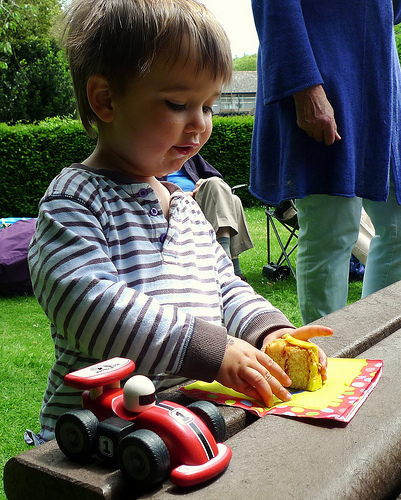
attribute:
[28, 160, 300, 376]
shirt — long sleeve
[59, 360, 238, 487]
car — toy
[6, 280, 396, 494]
table — brown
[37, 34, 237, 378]
boy — little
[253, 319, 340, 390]
cake — yellow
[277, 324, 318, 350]
frosting — yellow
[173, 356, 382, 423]
napkin — yellow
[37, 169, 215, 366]
stripes — shirt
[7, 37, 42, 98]
tree — large, green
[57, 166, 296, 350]
shirt — long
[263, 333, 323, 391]
cake — white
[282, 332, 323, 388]
frosting — yellow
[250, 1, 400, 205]
shirt — long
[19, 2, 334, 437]
boy — little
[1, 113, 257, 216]
bush — green, trimmed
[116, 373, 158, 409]
helmet — white, black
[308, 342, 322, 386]
frosting — yellow